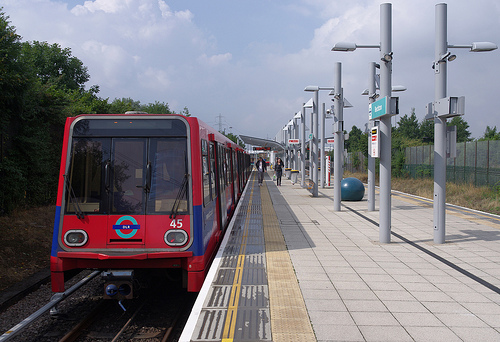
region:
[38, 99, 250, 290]
Red train on the tracks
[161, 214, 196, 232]
#45 written on the front of the train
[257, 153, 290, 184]
People walking on the platform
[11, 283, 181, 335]
Train tracks made of metal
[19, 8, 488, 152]
Fluffy clouds in the sky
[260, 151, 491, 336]
Train platform made of concrete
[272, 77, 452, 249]
Light posts lining the platform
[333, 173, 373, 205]
Large teal, decorative ball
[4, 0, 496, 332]
Photo taken during the day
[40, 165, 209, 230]
Two windshield wipers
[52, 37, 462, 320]
a train platform for passengers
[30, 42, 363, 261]
a sunny day for train riding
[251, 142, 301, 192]
passengers walking down the platform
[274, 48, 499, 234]
light poles on the platform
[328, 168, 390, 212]
a black decorative stone ball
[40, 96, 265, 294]
the train is red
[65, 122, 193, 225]
the conducter cannot be seen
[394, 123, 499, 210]
fence along the platform area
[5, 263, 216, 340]
tracks near the platform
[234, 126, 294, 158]
terminal point for the train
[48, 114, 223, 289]
red and blue train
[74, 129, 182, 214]
glass windshield on train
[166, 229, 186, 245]
head light on train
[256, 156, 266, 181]
person walking on sidewalk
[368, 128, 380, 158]
sign hanging on pole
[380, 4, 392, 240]
grey metal lamp post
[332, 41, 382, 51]
grey light on post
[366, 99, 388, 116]
green and white street sign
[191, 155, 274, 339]
metal grates by train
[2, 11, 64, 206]
tree with green leaves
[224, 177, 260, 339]
Yellow lines on the platform.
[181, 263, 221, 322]
White line on the platform.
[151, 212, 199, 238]
45 on the train.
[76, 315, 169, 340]
The tracks are brown.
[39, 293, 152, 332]
Gravel around the tracks.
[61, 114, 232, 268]
The train is mostly red.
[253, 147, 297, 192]
People on the platform.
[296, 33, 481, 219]
The light posts are grey.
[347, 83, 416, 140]
Sign on the light post.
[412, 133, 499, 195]
Fence on the right.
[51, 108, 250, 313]
a red and blue train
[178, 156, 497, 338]
a passenger boarding platform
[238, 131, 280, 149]
an overhead passenger shelter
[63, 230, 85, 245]
a train's front headlight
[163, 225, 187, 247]
a train's front headlight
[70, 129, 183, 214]
a train's front windshield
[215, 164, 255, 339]
a long yellow stripe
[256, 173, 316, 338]
a long yellow stripe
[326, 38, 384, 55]
an overhead platform light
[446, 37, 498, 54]
a long yellow stripe